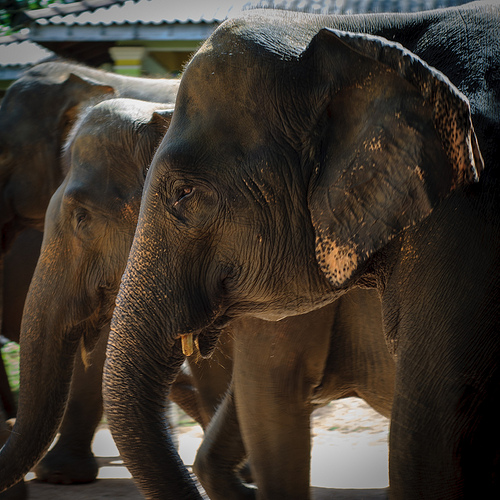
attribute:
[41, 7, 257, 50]
roof — ridged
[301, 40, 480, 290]
ear — pink, grey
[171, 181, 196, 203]
eye — elephant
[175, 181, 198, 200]
eye — brown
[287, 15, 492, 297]
ear — big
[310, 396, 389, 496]
dirt — tan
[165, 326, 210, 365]
short tusk — white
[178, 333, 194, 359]
tusk — small